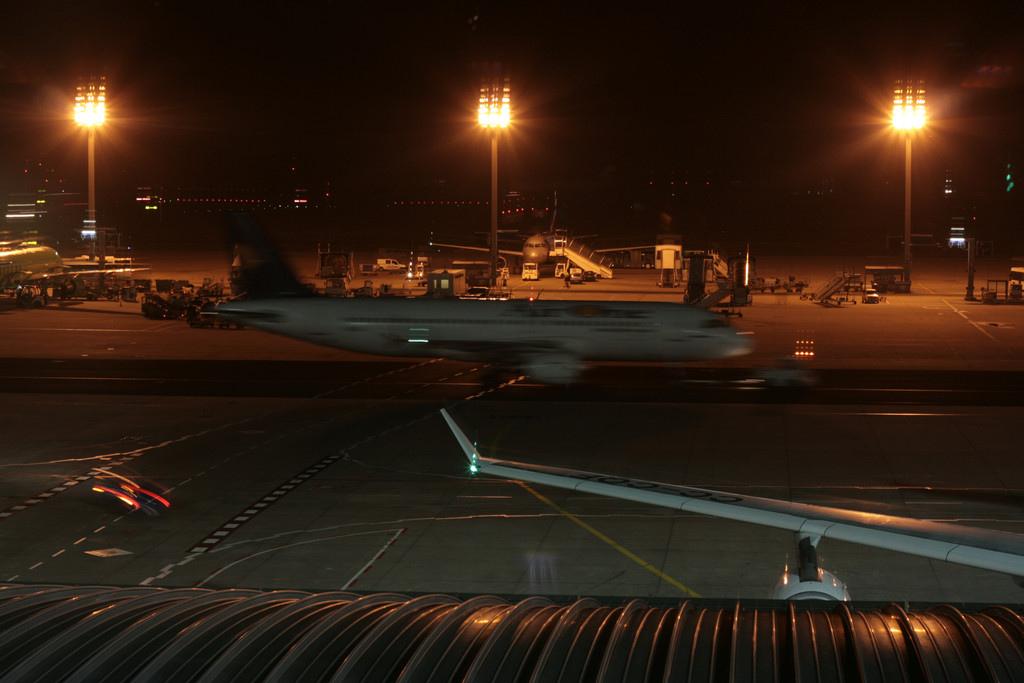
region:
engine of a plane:
[762, 568, 855, 604]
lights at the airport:
[59, 69, 939, 291]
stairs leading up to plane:
[552, 240, 619, 280]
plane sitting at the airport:
[424, 186, 662, 273]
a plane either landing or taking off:
[193, 196, 760, 403]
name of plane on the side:
[508, 295, 658, 321]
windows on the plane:
[338, 310, 655, 330]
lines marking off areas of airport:
[3, 353, 541, 587]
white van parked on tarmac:
[372, 253, 410, 274]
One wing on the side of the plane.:
[418, 379, 988, 615]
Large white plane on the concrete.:
[187, 206, 757, 428]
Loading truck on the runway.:
[64, 262, 142, 317]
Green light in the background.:
[991, 154, 1017, 203]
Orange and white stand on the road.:
[81, 452, 192, 525]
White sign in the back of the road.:
[936, 218, 971, 250]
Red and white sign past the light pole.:
[114, 174, 175, 217]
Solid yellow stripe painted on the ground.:
[550, 481, 693, 589]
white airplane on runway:
[188, 215, 784, 419]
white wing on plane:
[420, 382, 1016, 620]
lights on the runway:
[59, 81, 120, 133]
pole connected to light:
[75, 129, 114, 232]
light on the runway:
[460, 81, 537, 145]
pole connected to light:
[473, 136, 513, 267]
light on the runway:
[896, 75, 934, 142]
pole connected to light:
[893, 133, 935, 288]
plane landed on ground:
[496, 224, 617, 300]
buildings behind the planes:
[123, 170, 321, 240]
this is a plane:
[144, 218, 800, 425]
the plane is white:
[145, 202, 801, 431]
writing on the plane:
[485, 291, 678, 336]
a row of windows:
[338, 286, 680, 344]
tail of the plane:
[192, 180, 361, 310]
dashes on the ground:
[36, 402, 248, 579]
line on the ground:
[477, 458, 728, 610]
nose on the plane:
[725, 314, 763, 368]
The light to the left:
[27, 70, 176, 248]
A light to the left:
[45, 70, 154, 235]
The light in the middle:
[445, 73, 562, 242]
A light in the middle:
[447, 69, 562, 238]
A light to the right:
[851, 70, 969, 251]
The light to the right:
[845, 70, 972, 232]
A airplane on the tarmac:
[167, 215, 785, 387]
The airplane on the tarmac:
[169, 231, 786, 413]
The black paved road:
[36, 260, 1017, 616]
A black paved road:
[23, 270, 1017, 578]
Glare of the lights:
[884, 78, 939, 142]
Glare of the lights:
[471, 78, 523, 135]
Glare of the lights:
[69, 81, 115, 127]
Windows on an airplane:
[340, 310, 405, 343]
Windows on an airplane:
[514, 309, 594, 339]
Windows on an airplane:
[360, 315, 455, 338]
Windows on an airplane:
[438, 307, 497, 340]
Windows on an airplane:
[594, 315, 665, 342]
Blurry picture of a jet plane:
[217, 214, 761, 392]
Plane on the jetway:
[6, 203, 1022, 400]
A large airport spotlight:
[69, 67, 108, 267]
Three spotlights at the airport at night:
[73, 75, 933, 300]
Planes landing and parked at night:
[9, 6, 1009, 667]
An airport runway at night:
[22, 355, 1016, 404]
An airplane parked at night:
[426, 212, 677, 289]